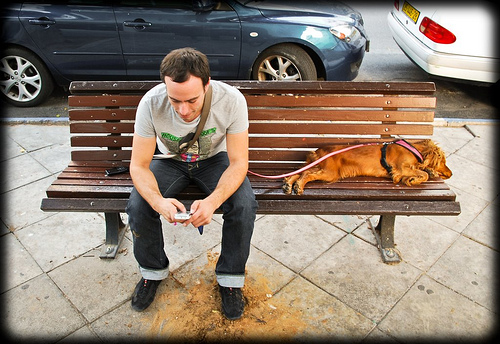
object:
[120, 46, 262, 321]
man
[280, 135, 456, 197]
dog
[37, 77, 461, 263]
bench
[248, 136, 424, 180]
leash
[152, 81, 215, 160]
bag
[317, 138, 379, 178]
fur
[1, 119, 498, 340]
sidewalk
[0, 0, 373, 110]
car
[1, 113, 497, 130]
curb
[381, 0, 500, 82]
car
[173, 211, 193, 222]
object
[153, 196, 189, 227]
hands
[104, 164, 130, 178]
phone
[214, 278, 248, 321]
foot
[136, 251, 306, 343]
dirt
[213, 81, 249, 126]
shoulder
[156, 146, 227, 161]
waist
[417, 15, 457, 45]
light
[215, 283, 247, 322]
sneakers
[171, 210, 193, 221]
cellphone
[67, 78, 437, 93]
slats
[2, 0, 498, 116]
traffic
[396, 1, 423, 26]
tag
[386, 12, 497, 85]
bumper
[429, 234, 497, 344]
tile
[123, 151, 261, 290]
jeans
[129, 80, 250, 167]
tee